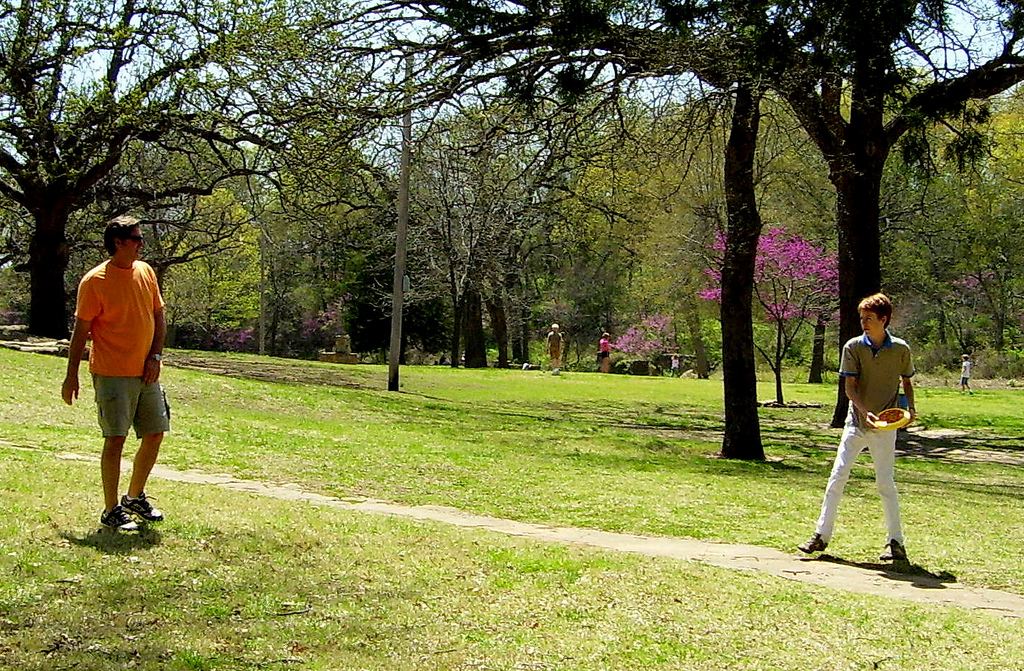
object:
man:
[59, 212, 172, 533]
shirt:
[72, 258, 170, 377]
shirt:
[837, 328, 916, 432]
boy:
[792, 290, 918, 565]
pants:
[867, 428, 906, 547]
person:
[544, 323, 565, 376]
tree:
[381, 0, 672, 371]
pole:
[385, 104, 413, 398]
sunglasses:
[129, 234, 146, 241]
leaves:
[625, 211, 626, 214]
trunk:
[829, 158, 891, 425]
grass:
[6, 346, 1019, 671]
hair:
[853, 291, 896, 330]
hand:
[859, 409, 880, 429]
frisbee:
[873, 407, 911, 434]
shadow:
[793, 554, 958, 591]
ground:
[0, 302, 920, 668]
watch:
[149, 353, 166, 362]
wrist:
[145, 352, 165, 362]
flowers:
[794, 247, 805, 255]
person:
[597, 331, 616, 373]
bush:
[610, 314, 687, 376]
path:
[52, 446, 1024, 622]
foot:
[797, 532, 829, 554]